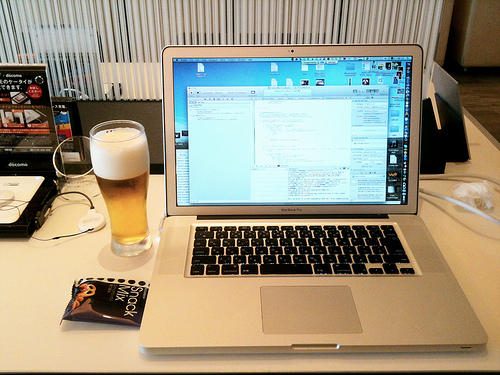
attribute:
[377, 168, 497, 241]
cable — white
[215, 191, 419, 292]
keyboard — black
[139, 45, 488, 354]
computer — laptop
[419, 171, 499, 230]
cord — white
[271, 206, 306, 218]
letters — black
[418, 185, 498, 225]
power cord — white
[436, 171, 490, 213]
tissue — crumbled up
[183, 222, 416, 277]
computer keys — black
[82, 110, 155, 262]
glass — clear, full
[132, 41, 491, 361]
laptop — silver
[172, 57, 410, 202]
laptop screen — lit up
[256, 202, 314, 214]
logo — small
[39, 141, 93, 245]
cords — several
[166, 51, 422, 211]
screen — lit up